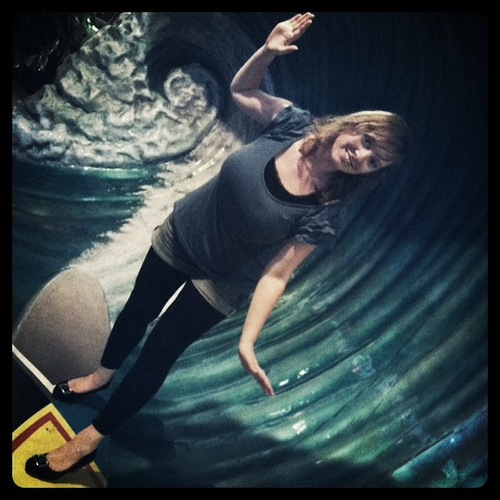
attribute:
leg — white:
[66, 424, 103, 461]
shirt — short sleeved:
[142, 101, 376, 313]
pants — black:
[87, 290, 190, 466]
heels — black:
[24, 444, 99, 481]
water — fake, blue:
[55, 30, 225, 221]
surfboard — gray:
[8, 249, 159, 494]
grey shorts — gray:
[151, 210, 246, 313]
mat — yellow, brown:
[13, 428, 56, 454]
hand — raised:
[265, 8, 314, 53]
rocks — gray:
[10, 18, 205, 160]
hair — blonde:
[296, 108, 411, 181]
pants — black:
[91, 244, 226, 438]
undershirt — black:
[264, 156, 324, 207]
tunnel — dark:
[14, 10, 485, 489]